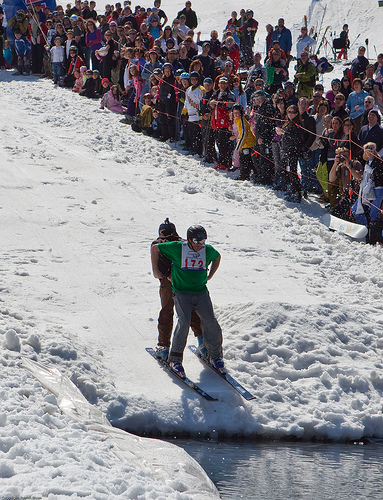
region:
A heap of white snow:
[25, 216, 116, 306]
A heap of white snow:
[36, 425, 153, 493]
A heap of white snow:
[4, 313, 88, 402]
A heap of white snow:
[245, 343, 295, 413]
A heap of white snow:
[280, 328, 346, 411]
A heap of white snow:
[311, 259, 375, 326]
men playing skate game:
[136, 206, 261, 417]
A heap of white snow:
[227, 199, 289, 259]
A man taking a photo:
[332, 143, 368, 215]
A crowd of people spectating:
[133, 33, 277, 158]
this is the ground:
[29, 178, 88, 235]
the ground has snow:
[51, 173, 107, 232]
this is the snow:
[74, 217, 126, 285]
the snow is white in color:
[88, 233, 116, 277]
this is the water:
[261, 448, 317, 475]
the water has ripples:
[243, 448, 325, 478]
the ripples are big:
[264, 460, 330, 487]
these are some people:
[27, 6, 361, 177]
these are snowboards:
[179, 364, 267, 399]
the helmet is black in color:
[193, 226, 201, 231]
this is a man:
[166, 218, 228, 367]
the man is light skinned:
[144, 248, 157, 274]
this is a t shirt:
[162, 239, 183, 280]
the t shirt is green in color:
[162, 241, 172, 256]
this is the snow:
[5, 110, 69, 296]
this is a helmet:
[195, 223, 209, 236]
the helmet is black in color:
[190, 225, 207, 247]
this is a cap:
[216, 75, 230, 81]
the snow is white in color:
[24, 112, 97, 272]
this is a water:
[263, 449, 341, 498]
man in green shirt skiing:
[146, 217, 237, 380]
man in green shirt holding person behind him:
[141, 221, 237, 384]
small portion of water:
[132, 414, 379, 497]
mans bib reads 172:
[177, 238, 211, 272]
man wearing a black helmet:
[183, 221, 212, 246]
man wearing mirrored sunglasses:
[188, 235, 209, 245]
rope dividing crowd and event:
[140, 62, 382, 210]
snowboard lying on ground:
[317, 208, 371, 239]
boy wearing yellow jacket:
[228, 101, 261, 183]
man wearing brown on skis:
[148, 215, 213, 363]